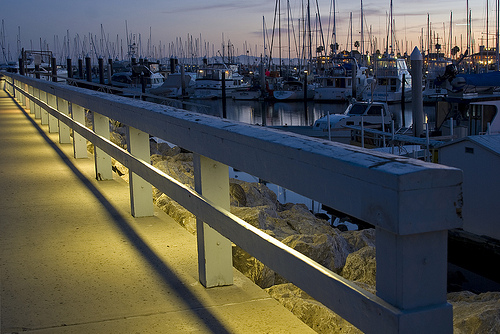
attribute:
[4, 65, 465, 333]
guard rail — wooden, white, thick, long, lit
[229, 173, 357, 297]
rocks — gray, here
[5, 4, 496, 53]
sky — blue, pink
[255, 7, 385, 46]
clouds — purple, blue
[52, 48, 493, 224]
boats — white, double decker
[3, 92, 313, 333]
sidewalk — gray, concrete, cement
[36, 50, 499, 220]
bay — here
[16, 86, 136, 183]
lighting — glowing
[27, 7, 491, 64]
masts — here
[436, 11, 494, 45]
sun — rising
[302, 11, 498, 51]
sunset — orange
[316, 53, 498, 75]
lights — bright, glowing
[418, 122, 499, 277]
house — white